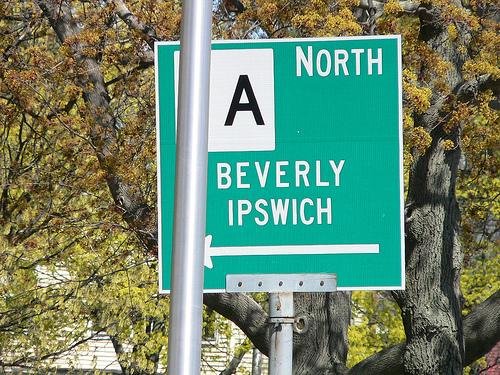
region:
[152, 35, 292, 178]
a white box on a sign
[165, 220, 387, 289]
a white arrow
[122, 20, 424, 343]
a green and white street sign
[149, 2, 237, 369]
a metal pole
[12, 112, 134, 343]
green pine tree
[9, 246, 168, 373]
building behind the trees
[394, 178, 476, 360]
a brown tree branch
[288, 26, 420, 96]
a white north on a green sign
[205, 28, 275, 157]
a black A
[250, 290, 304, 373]
metal pole holding the sign up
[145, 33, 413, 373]
a directional sign is on a pole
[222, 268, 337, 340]
the sign is bolted the pole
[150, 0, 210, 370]
a steel pole is in front of the sign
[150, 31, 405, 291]
the sign has a green background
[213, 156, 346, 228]
white lettering is on the sign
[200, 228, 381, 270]
a white arrow is on the sign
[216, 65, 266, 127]
a black letter is on the sign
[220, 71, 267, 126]
the capital letter is black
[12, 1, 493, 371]
a tree is behind the sign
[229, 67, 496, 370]
the tree has large branches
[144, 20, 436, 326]
green sign with white writing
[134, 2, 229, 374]
silver metal pole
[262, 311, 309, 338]
metal bracket on sign post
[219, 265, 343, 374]
metal sign post with rust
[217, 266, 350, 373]
galvanized metal sign post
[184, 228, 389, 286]
white arrow on green sign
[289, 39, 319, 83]
white letter on sign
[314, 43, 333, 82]
white letter on sign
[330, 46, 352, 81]
white letter on sign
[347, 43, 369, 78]
white letter on sign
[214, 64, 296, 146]
black letter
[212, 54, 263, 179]
black letter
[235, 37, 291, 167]
black letter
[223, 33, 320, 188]
black letter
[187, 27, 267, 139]
black letter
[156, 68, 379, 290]
sign is green and white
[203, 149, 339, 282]
town names are white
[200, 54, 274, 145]
road is labeled black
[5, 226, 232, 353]
white building behind sign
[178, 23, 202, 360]
metal pole in front of sign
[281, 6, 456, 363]
thick tree behind sign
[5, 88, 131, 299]
tree has orange and green leaves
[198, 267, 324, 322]
metal clamp on bottom of sign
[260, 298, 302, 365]
metal pole below sign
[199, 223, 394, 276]
arrow on sign points left